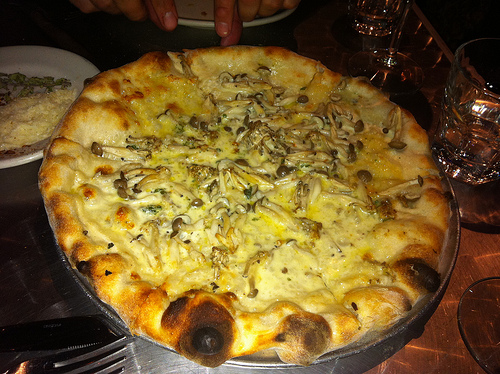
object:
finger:
[210, 9, 242, 45]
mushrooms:
[187, 197, 206, 210]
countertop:
[4, 5, 498, 365]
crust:
[157, 289, 238, 372]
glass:
[459, 101, 482, 111]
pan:
[52, 45, 462, 366]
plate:
[455, 269, 498, 372]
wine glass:
[436, 49, 496, 181]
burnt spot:
[180, 307, 200, 324]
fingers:
[145, 0, 180, 26]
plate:
[1, 38, 113, 187]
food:
[2, 69, 83, 159]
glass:
[458, 67, 478, 94]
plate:
[143, 0, 290, 40]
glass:
[473, 135, 492, 156]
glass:
[368, 43, 392, 62]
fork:
[33, 335, 129, 373]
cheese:
[235, 214, 261, 250]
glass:
[469, 146, 498, 176]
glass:
[362, 34, 389, 52]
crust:
[277, 304, 334, 366]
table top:
[11, 9, 498, 371]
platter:
[46, 40, 466, 365]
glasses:
[354, 0, 413, 41]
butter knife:
[0, 309, 112, 353]